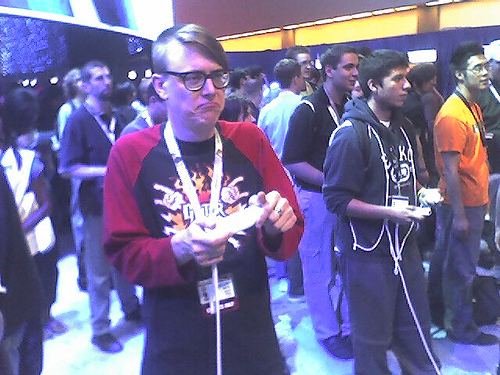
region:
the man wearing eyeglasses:
[164, 53, 250, 135]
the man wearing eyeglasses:
[121, 30, 267, 140]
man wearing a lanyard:
[141, 116, 241, 252]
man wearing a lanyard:
[455, 98, 499, 156]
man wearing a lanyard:
[71, 100, 152, 160]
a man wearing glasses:
[112, 37, 237, 138]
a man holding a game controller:
[128, 47, 276, 276]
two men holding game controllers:
[98, 58, 453, 295]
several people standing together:
[26, 65, 471, 265]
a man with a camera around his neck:
[453, 43, 493, 194]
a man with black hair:
[362, 48, 417, 117]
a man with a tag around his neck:
[173, 45, 235, 316]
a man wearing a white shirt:
[266, 57, 303, 141]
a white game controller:
[182, 189, 289, 253]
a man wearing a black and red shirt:
[91, 30, 293, 280]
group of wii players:
[53, 16, 450, 374]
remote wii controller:
[150, 195, 277, 372]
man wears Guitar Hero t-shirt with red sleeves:
[72, 120, 307, 350]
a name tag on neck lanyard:
[190, 268, 255, 323]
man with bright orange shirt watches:
[420, 41, 491, 212]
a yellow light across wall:
[210, 0, 491, 60]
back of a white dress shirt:
[252, 33, 319, 154]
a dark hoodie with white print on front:
[316, 93, 432, 279]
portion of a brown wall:
[171, 2, 413, 42]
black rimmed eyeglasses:
[151, 62, 232, 93]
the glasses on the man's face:
[159, 66, 231, 91]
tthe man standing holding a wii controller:
[103, 23, 305, 373]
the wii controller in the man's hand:
[205, 204, 262, 239]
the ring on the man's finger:
[273, 205, 283, 215]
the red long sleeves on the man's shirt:
[102, 120, 304, 287]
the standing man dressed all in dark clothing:
[320, 50, 442, 373]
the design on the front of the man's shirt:
[151, 161, 248, 250]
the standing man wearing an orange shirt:
[431, 39, 496, 342]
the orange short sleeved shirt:
[432, 92, 488, 204]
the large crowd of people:
[1, 23, 499, 373]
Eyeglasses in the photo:
[179, 55, 231, 91]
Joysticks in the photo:
[193, 198, 268, 236]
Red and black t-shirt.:
[92, 135, 285, 264]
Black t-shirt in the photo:
[282, 99, 339, 159]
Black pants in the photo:
[344, 262, 401, 370]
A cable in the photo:
[391, 259, 450, 369]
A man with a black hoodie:
[318, 109, 424, 252]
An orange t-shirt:
[430, 91, 496, 210]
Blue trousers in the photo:
[81, 222, 137, 332]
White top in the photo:
[0, 149, 55, 254]